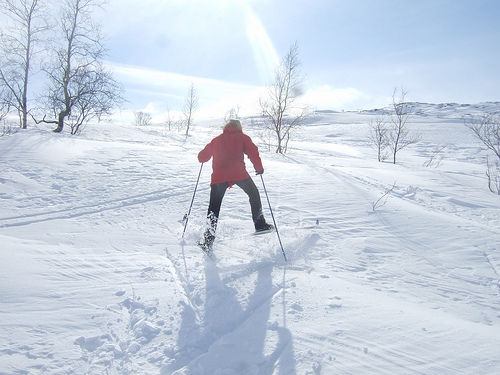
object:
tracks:
[161, 280, 288, 374]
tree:
[386, 87, 424, 166]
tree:
[372, 121, 389, 162]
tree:
[265, 47, 304, 152]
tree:
[181, 82, 199, 138]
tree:
[67, 75, 112, 137]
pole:
[260, 174, 290, 262]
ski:
[89, 111, 385, 303]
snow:
[5, 136, 496, 375]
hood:
[223, 126, 241, 132]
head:
[224, 119, 242, 131]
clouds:
[2, 0, 499, 126]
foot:
[197, 234, 215, 252]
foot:
[254, 224, 273, 232]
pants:
[200, 180, 266, 240]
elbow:
[197, 153, 207, 163]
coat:
[197, 128, 264, 183]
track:
[0, 195, 168, 229]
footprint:
[123, 170, 140, 173]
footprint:
[50, 183, 62, 191]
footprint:
[67, 162, 81, 165]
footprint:
[93, 161, 115, 167]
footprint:
[130, 159, 146, 162]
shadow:
[179, 253, 294, 373]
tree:
[45, 0, 122, 136]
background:
[1, 1, 499, 137]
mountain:
[269, 102, 500, 124]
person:
[188, 120, 274, 249]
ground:
[0, 136, 500, 374]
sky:
[134, 8, 402, 75]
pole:
[183, 162, 205, 238]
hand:
[254, 167, 265, 175]